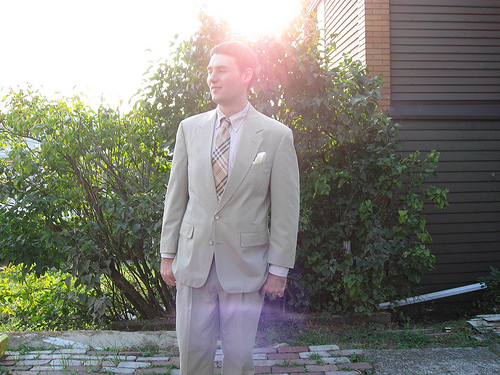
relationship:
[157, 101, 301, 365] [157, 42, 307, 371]
suit on man